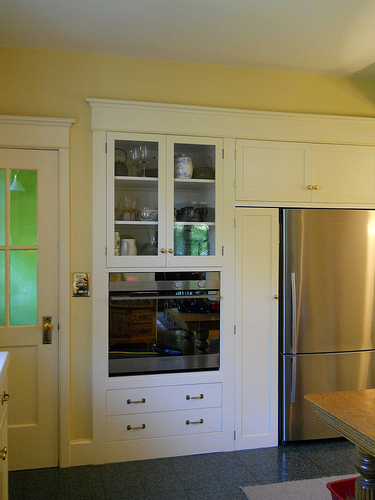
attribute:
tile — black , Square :
[232, 441, 310, 482]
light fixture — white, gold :
[7, 171, 27, 191]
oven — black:
[109, 270, 216, 369]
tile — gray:
[192, 458, 242, 492]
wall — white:
[69, 162, 102, 276]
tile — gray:
[238, 457, 292, 483]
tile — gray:
[214, 461, 255, 484]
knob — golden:
[36, 315, 58, 346]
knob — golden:
[312, 185, 320, 190]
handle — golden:
[299, 180, 329, 196]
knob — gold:
[42, 318, 61, 339]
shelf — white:
[112, 169, 216, 187]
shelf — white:
[112, 215, 217, 230]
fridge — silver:
[278, 208, 372, 445]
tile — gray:
[8, 437, 358, 498]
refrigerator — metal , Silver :
[270, 196, 373, 460]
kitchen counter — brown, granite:
[301, 383, 373, 446]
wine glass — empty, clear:
[137, 142, 152, 178]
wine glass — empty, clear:
[125, 144, 141, 177]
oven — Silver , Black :
[113, 269, 221, 312]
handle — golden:
[167, 245, 172, 254]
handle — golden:
[165, 247, 174, 256]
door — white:
[3, 112, 80, 473]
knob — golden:
[166, 246, 176, 254]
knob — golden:
[157, 245, 167, 255]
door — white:
[0, 141, 59, 475]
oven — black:
[106, 269, 223, 378]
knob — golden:
[157, 246, 167, 254]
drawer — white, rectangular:
[102, 405, 219, 443]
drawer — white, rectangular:
[105, 382, 222, 416]